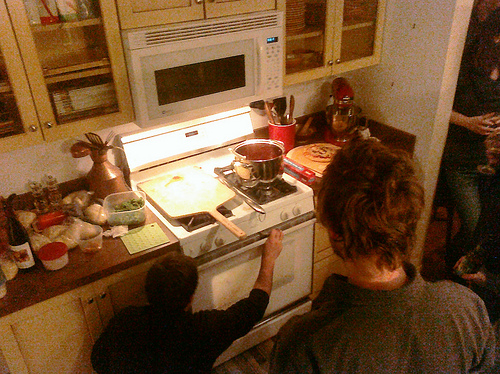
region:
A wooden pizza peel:
[133, 165, 258, 248]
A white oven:
[116, 114, 314, 363]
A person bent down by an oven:
[81, 221, 285, 370]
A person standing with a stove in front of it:
[277, 128, 497, 373]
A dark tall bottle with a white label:
[2, 195, 46, 276]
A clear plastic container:
[100, 187, 150, 222]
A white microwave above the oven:
[131, 20, 286, 121]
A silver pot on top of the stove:
[225, 140, 287, 195]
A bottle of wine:
[0, 200, 50, 273]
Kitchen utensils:
[72, 133, 132, 187]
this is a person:
[269, 139, 498, 364]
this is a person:
[89, 221, 278, 364]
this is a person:
[434, 47, 496, 293]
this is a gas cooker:
[154, 150, 324, 310]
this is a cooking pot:
[231, 131, 291, 198]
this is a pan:
[138, 159, 255, 261]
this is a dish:
[101, 187, 158, 239]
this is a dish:
[26, 239, 83, 274]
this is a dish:
[77, 221, 114, 258]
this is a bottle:
[3, 202, 41, 286]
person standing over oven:
[281, 136, 478, 372]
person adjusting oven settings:
[82, 225, 291, 372]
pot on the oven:
[223, 138, 291, 186]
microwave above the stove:
[128, 55, 286, 109]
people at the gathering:
[457, 56, 495, 288]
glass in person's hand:
[477, 100, 499, 181]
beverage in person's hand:
[447, 226, 495, 282]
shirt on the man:
[276, 269, 483, 370]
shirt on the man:
[93, 298, 265, 372]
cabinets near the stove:
[3, 272, 178, 372]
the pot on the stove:
[213, 131, 288, 202]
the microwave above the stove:
[123, 1, 308, 111]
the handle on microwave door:
[246, 35, 274, 95]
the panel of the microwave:
[256, 33, 289, 97]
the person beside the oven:
[108, 217, 280, 372]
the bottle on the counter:
[1, 193, 43, 280]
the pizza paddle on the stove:
[133, 170, 258, 268]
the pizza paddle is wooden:
[131, 154, 246, 252]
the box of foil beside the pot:
[276, 153, 318, 185]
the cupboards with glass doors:
[2, 3, 131, 132]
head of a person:
[283, 148, 425, 250]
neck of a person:
[340, 253, 435, 294]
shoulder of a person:
[272, 271, 494, 363]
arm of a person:
[230, 226, 300, 320]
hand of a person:
[237, 226, 302, 280]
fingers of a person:
[257, 222, 287, 250]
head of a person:
[142, 251, 213, 308]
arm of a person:
[442, 83, 496, 134]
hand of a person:
[470, 102, 497, 134]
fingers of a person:
[472, 112, 499, 146]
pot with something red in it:
[229, 132, 287, 194]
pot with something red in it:
[224, 126, 297, 196]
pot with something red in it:
[220, 134, 301, 191]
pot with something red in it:
[221, 130, 303, 201]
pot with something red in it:
[215, 131, 309, 193]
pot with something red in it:
[214, 130, 301, 202]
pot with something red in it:
[212, 125, 303, 200]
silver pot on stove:
[226, 138, 309, 201]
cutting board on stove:
[136, 155, 285, 265]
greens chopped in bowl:
[93, 180, 160, 237]